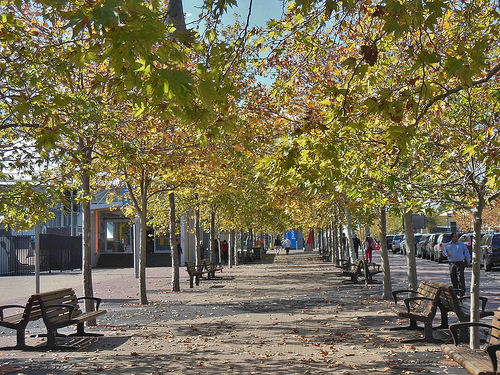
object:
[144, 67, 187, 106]
leaf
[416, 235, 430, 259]
car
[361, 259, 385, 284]
bench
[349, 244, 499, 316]
road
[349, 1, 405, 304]
tree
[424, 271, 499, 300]
shadow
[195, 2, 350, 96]
sky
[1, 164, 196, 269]
buidling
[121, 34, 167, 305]
tree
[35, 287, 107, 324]
wood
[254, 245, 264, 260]
table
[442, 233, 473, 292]
man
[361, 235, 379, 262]
woman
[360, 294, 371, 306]
leaf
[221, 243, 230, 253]
shirt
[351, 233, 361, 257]
man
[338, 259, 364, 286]
bench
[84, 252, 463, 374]
pavement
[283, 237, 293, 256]
person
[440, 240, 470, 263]
shirt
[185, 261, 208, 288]
bench